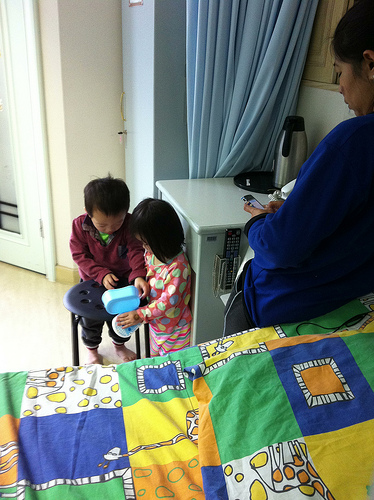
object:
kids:
[68, 176, 191, 360]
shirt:
[127, 253, 226, 348]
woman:
[276, 28, 359, 299]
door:
[0, 0, 55, 278]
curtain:
[184, 0, 320, 178]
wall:
[55, 43, 113, 112]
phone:
[241, 195, 266, 215]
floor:
[0, 262, 96, 370]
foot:
[76, 338, 137, 374]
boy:
[69, 175, 149, 368]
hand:
[115, 308, 147, 327]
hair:
[83, 178, 129, 218]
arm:
[70, 215, 118, 291]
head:
[128, 275, 184, 338]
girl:
[116, 197, 192, 359]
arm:
[247, 117, 364, 269]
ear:
[363, 50, 374, 84]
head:
[330, 86, 374, 194]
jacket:
[69, 289, 155, 361]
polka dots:
[142, 252, 215, 329]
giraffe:
[247, 441, 330, 499]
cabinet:
[156, 173, 291, 349]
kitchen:
[40, 67, 373, 403]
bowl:
[101, 285, 140, 315]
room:
[47, 31, 310, 475]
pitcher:
[274, 115, 307, 196]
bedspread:
[0, 288, 373, 498]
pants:
[79, 296, 132, 349]